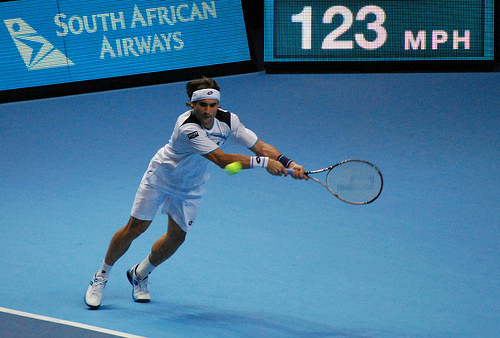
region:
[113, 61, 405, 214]
a man holding a tennis racket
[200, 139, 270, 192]
a yellow tennis ball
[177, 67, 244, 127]
a man with brown hair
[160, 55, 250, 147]
a man wearing a white head band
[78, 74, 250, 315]
a man wearing white tennis shoes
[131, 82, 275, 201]
a man wearing a white shirt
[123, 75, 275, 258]
a man wearing white shorts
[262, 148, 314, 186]
a man wearing a blue wrist band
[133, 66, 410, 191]
a man stretching his arms out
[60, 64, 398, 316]
a man playing tennis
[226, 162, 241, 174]
a green tennis ball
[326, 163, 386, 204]
a tennis racket that is black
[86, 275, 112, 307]
white tennis shoes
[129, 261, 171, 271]
man is wearing white socks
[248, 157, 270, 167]
a white wrist band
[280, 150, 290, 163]
a black wrist band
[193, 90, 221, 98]
a white hand band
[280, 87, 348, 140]
the floor is blue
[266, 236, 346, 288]
it is a blue tennis court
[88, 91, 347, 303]
the man is playing tennis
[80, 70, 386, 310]
A MAN PLAYING TENNIS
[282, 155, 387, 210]
A TENNIS RACKET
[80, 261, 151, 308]
A PAIR OF TENNIS SHOES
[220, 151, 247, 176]
A GREEN TENNIS BALL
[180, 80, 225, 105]
A WHITE SWEAT BAND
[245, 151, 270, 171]
A WHITE WRIST BAND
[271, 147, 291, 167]
A BLACK WRIST BAND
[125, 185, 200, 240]
A PAIR OF WHITE SHORTS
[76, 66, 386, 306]
A PICTURE OF A MAN PLAYING TENNIS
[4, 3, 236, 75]
SOUTH AFRICAN AIRWAYS ADVERTISEMENT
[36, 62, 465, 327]
the player is playing tennis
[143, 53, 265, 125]
the player is wearing headband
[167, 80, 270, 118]
the headband is white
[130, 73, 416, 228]
the player is holding a racket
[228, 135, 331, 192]
racket handle is blue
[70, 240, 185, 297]
the socks are white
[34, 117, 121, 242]
the tennis floor is blue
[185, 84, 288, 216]
the player will hit the ball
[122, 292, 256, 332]
shadow on the ground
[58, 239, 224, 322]
player is wearing tennis shoes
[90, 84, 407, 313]
man playing tennis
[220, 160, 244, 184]
tennis ball that the tennis player is trying to hit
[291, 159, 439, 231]
tennis racket that the man playing tennis is swinging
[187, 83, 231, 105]
hite headband that the tennis player is wearing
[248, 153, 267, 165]
white wrist cuff that the tennis player is wearing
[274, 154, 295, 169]
black wrist cuff that the man playing tennis is wearing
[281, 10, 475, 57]
speed sign indicating how fast the tennis ball is traveling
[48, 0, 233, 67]
advertising sign for South African Airways on the wall behind the tennis player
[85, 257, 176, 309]
white shoes that the tennis player is wearing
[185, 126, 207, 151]
logo on the sleeve of the white shirt that the tennis player is wearing